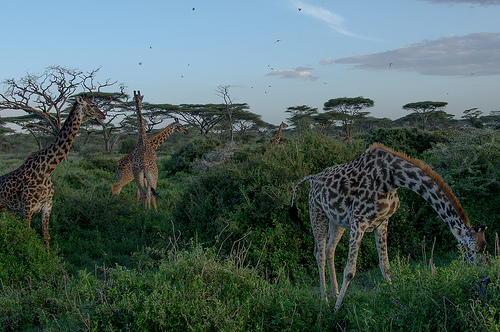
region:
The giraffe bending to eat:
[282, 135, 487, 310]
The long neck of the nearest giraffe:
[375, 133, 479, 252]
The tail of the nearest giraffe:
[283, 170, 322, 227]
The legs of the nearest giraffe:
[305, 205, 402, 312]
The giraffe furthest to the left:
[0, 90, 110, 257]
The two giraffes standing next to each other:
[109, 81, 190, 216]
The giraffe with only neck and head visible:
[269, 117, 291, 149]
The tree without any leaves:
[0, 62, 131, 146]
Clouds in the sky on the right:
[262, 17, 499, 87]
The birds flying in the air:
[129, 32, 398, 100]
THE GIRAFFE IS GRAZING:
[237, 135, 497, 311]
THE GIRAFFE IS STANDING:
[0, 81, 115, 256]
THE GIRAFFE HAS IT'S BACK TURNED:
[125, 75, 175, 215]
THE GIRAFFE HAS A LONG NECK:
[391, 146, 467, 272]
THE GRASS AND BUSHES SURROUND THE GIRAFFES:
[12, 135, 493, 330]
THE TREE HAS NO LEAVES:
[0, 56, 105, 161]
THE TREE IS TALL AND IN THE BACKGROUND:
[308, 87, 379, 153]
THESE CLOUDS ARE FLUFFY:
[270, 10, 498, 103]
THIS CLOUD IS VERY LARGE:
[265, 22, 497, 87]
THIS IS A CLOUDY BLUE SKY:
[2, 1, 499, 127]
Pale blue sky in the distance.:
[129, 15, 252, 68]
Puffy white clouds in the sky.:
[256, 48, 346, 83]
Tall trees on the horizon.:
[194, 93, 466, 135]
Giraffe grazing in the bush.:
[261, 126, 490, 303]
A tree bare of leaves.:
[5, 39, 82, 134]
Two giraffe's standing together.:
[103, 70, 188, 218]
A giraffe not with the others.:
[267, 112, 290, 159]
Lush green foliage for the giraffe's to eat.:
[180, 155, 261, 241]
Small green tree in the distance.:
[169, 129, 226, 181]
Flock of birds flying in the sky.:
[252, 33, 290, 107]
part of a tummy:
[318, 178, 348, 217]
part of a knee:
[341, 254, 359, 302]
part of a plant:
[202, 269, 228, 306]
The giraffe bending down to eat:
[282, 133, 491, 317]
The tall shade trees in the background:
[6, 92, 483, 137]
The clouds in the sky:
[262, 0, 498, 85]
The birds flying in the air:
[132, 2, 478, 111]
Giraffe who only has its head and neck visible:
[269, 117, 294, 146]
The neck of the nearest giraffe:
[390, 152, 470, 237]